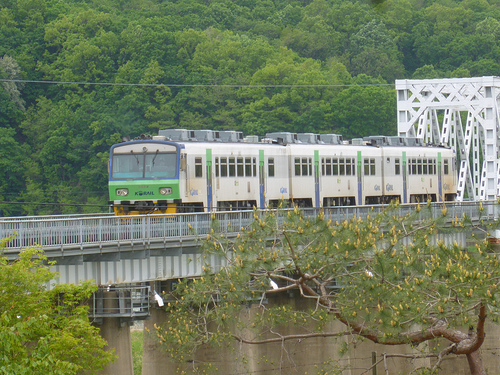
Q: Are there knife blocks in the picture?
A: No, there are no knife blocks.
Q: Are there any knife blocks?
A: No, there are no knife blocks.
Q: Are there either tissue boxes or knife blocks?
A: No, there are no knife blocks or tissue boxes.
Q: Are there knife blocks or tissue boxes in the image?
A: No, there are no knife blocks or tissue boxes.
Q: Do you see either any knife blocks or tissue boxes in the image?
A: No, there are no knife blocks or tissue boxes.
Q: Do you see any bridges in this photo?
A: Yes, there is a bridge.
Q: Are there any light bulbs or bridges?
A: Yes, there is a bridge.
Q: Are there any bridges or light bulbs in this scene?
A: Yes, there is a bridge.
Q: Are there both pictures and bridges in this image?
A: Yes, there are both a bridge and a picture.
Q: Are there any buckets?
A: No, there are no buckets.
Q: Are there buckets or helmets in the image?
A: No, there are no buckets or helmets.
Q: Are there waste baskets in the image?
A: No, there are no waste baskets.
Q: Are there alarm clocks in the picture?
A: No, there are no alarm clocks.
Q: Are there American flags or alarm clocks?
A: No, there are no alarm clocks or American flags.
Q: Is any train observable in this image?
A: Yes, there is a train.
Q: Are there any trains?
A: Yes, there is a train.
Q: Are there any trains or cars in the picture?
A: Yes, there is a train.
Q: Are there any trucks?
A: No, there are no trucks.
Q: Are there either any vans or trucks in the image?
A: No, there are no trucks or vans.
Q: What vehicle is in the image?
A: The vehicle is a train.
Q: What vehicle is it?
A: The vehicle is a train.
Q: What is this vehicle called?
A: This is a train.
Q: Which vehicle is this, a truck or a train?
A: This is a train.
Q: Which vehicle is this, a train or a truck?
A: This is a train.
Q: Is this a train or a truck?
A: This is a train.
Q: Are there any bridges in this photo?
A: Yes, there is a bridge.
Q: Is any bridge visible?
A: Yes, there is a bridge.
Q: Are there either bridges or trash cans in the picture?
A: Yes, there is a bridge.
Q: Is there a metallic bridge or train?
A: Yes, there is a metal bridge.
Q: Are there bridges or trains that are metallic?
A: Yes, the bridge is metallic.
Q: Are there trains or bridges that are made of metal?
A: Yes, the bridge is made of metal.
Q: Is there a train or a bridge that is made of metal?
A: Yes, the bridge is made of metal.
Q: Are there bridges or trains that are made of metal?
A: Yes, the bridge is made of metal.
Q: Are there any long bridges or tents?
A: Yes, there is a long bridge.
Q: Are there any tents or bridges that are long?
A: Yes, the bridge is long.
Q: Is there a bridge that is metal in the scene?
A: Yes, there is a metal bridge.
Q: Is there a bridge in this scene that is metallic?
A: Yes, there is a bridge that is metallic.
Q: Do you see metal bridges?
A: Yes, there is a bridge that is made of metal.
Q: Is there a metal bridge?
A: Yes, there is a bridge that is made of metal.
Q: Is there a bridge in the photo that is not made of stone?
A: Yes, there is a bridge that is made of metal.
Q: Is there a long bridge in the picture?
A: Yes, there is a long bridge.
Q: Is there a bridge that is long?
A: Yes, there is a bridge that is long.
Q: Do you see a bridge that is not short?
A: Yes, there is a long bridge.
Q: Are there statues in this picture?
A: No, there are no statues.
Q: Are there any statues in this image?
A: No, there are no statues.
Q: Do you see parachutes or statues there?
A: No, there are no statues or parachutes.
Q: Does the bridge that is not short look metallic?
A: Yes, the bridge is metallic.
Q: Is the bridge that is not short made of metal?
A: Yes, the bridge is made of metal.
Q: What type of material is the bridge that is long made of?
A: The bridge is made of metal.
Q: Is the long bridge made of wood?
A: No, the bridge is made of metal.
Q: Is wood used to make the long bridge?
A: No, the bridge is made of metal.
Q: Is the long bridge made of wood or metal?
A: The bridge is made of metal.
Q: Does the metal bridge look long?
A: Yes, the bridge is long.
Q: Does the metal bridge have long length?
A: Yes, the bridge is long.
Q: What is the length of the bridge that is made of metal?
A: The bridge is long.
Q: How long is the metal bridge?
A: The bridge is long.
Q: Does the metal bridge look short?
A: No, the bridge is long.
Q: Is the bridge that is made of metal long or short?
A: The bridge is long.